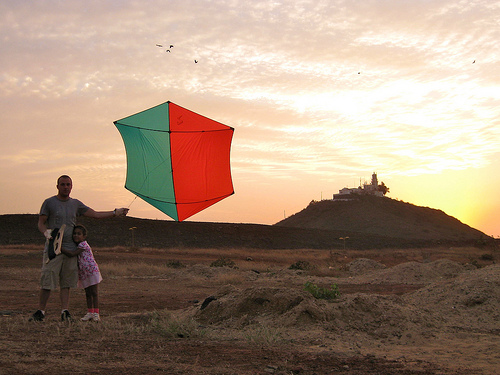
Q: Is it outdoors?
A: Yes, it is outdoors.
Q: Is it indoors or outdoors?
A: It is outdoors.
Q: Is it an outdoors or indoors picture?
A: It is outdoors.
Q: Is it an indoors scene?
A: No, it is outdoors.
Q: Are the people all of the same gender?
A: No, they are both male and female.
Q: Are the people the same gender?
A: No, they are both male and female.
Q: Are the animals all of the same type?
A: Yes, all the animals are birds.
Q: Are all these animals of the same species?
A: Yes, all the animals are birds.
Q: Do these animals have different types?
A: No, all the animals are birds.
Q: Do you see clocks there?
A: No, there are no clocks.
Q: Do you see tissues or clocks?
A: No, there are no clocks or tissues.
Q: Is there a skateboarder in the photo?
A: No, there are no skateboarders.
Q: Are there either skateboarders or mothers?
A: No, there are no skateboarders or mothers.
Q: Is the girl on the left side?
A: Yes, the girl is on the left of the image.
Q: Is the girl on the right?
A: No, the girl is on the left of the image.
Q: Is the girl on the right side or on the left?
A: The girl is on the left of the image.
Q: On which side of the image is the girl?
A: The girl is on the left of the image.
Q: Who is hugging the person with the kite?
A: The girl is hugging the man.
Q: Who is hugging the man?
A: The girl is hugging the man.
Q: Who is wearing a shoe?
A: The girl is wearing a shoe.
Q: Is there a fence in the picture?
A: No, there are no fences.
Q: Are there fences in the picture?
A: No, there are no fences.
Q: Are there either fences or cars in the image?
A: No, there are no fences or cars.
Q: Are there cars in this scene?
A: No, there are no cars.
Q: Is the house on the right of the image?
A: Yes, the house is on the right of the image.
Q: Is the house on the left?
A: No, the house is on the right of the image.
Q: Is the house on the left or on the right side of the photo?
A: The house is on the right of the image.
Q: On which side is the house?
A: The house is on the right of the image.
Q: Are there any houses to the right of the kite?
A: Yes, there is a house to the right of the kite.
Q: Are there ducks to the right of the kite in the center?
A: No, there is a house to the right of the kite.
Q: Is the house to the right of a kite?
A: Yes, the house is to the right of a kite.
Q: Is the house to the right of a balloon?
A: No, the house is to the right of a kite.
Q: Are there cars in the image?
A: No, there are no cars.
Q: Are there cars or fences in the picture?
A: No, there are no cars or fences.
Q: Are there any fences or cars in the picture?
A: No, there are no cars or fences.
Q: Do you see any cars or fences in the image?
A: No, there are no cars or fences.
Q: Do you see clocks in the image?
A: No, there are no clocks.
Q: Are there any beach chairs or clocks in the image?
A: No, there are no clocks or beach chairs.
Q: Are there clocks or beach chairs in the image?
A: No, there are no clocks or beach chairs.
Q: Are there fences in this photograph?
A: No, there are no fences.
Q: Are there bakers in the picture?
A: No, there are no bakers.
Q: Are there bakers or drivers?
A: No, there are no bakers or drivers.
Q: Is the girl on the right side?
A: No, the girl is on the left of the image.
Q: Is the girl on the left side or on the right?
A: The girl is on the left of the image.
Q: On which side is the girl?
A: The girl is on the left of the image.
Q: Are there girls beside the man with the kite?
A: Yes, there is a girl beside the man.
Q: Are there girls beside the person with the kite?
A: Yes, there is a girl beside the man.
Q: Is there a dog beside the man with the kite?
A: No, there is a girl beside the man.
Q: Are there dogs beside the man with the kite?
A: No, there is a girl beside the man.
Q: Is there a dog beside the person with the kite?
A: No, there is a girl beside the man.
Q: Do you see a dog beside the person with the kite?
A: No, there is a girl beside the man.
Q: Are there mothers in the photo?
A: No, there are no mothers.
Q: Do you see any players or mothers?
A: No, there are no mothers or players.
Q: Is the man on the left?
A: Yes, the man is on the left of the image.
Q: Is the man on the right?
A: No, the man is on the left of the image.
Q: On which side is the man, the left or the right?
A: The man is on the left of the image.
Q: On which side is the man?
A: The man is on the left of the image.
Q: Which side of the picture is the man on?
A: The man is on the left of the image.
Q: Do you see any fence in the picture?
A: No, there are no fences.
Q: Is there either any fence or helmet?
A: No, there are no fences or helmets.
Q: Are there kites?
A: Yes, there is a kite.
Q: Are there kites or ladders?
A: Yes, there is a kite.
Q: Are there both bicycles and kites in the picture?
A: No, there is a kite but no bicycles.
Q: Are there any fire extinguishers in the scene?
A: No, there are no fire extinguishers.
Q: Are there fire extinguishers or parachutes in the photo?
A: No, there are no fire extinguishers or parachutes.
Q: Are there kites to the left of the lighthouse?
A: Yes, there is a kite to the left of the lighthouse.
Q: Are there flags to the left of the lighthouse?
A: No, there is a kite to the left of the lighthouse.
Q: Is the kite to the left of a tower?
A: No, the kite is to the left of the lighthouse.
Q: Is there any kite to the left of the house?
A: Yes, there is a kite to the left of the house.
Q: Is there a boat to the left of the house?
A: No, there is a kite to the left of the house.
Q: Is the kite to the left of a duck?
A: No, the kite is to the left of a house.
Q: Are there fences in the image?
A: No, there are no fences.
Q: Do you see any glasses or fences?
A: No, there are no fences or glasses.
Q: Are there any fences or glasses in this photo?
A: No, there are no fences or glasses.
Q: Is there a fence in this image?
A: No, there are no fences.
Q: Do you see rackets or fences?
A: No, there are no fences or rackets.